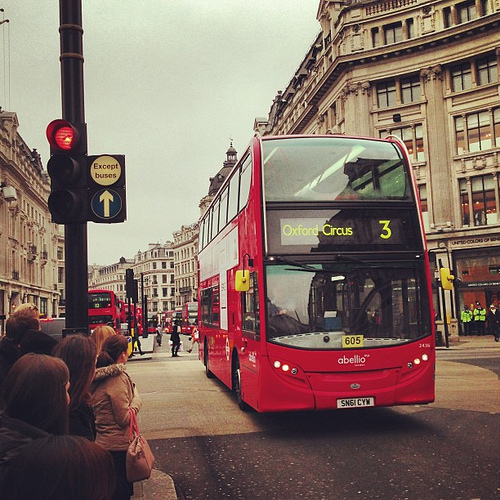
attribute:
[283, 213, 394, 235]
words — yellow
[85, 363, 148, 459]
coat — brown 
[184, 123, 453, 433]
bus — double decker, red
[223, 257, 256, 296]
mirror — yellow , black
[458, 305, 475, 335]
coat — neon green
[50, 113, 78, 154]
light — red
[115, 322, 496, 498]
road — black 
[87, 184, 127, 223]
sign — blue, white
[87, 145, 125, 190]
sign — white, black 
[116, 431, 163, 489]
purse — tan 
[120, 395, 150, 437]
handles — red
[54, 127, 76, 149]
light — red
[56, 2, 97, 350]
pole — black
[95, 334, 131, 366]
hair — brown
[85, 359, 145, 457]
coat — tan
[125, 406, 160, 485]
bag — large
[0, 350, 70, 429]
hair — brown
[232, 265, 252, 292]
mirror — yellow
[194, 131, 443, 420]
bus — large, red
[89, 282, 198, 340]
buses — red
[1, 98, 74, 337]
building — part 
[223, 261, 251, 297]
mirror — side , part 